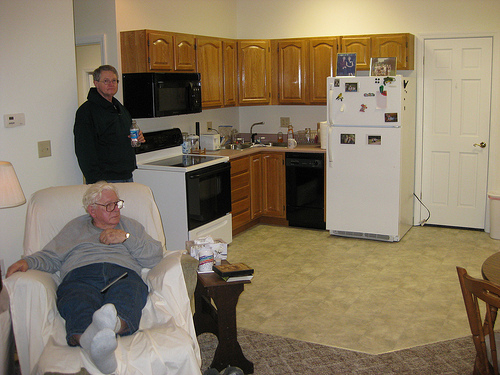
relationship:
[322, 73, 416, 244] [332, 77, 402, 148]
refrigerator has magnets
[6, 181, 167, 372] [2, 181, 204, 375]
man sitting in recliner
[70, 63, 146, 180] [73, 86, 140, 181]
man wearing jacket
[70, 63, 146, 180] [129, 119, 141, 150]
man drinking beverage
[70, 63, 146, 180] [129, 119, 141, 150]
man holding beverage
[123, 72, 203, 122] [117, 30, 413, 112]
microwave under cupboards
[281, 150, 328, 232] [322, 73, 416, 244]
dishwasher next to refrigerator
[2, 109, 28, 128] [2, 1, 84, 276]
thermostat on wall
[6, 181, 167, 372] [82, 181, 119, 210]
man has hair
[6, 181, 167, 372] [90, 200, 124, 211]
man has glasses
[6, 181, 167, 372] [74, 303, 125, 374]
man has socks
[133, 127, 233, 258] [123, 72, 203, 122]
range under microwave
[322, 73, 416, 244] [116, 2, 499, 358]
refrigerator in kitchen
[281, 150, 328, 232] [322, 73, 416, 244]
dishwasher beside refrigerator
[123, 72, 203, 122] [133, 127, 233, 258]
microwave above range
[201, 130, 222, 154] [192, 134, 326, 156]
toaster on top of counter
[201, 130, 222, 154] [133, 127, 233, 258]
toaster next to range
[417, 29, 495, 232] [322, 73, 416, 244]
door next to refrigerator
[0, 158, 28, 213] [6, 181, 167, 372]
lampshade beside man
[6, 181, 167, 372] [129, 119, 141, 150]
man has beverage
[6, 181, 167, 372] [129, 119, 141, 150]
man carrying beverage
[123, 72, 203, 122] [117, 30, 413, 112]
microwave mounted under cupboards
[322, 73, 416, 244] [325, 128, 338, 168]
refrigerator has handle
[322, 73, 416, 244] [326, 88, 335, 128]
refrigerator has handle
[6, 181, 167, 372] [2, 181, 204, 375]
man standing behind recliner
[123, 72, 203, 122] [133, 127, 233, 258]
microwave over range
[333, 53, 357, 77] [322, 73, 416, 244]
picture on top of refrigerator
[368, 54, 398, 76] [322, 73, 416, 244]
picture on top of refrigerator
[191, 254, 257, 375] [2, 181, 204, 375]
table next to recliner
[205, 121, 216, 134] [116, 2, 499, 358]
outlet in kitchen